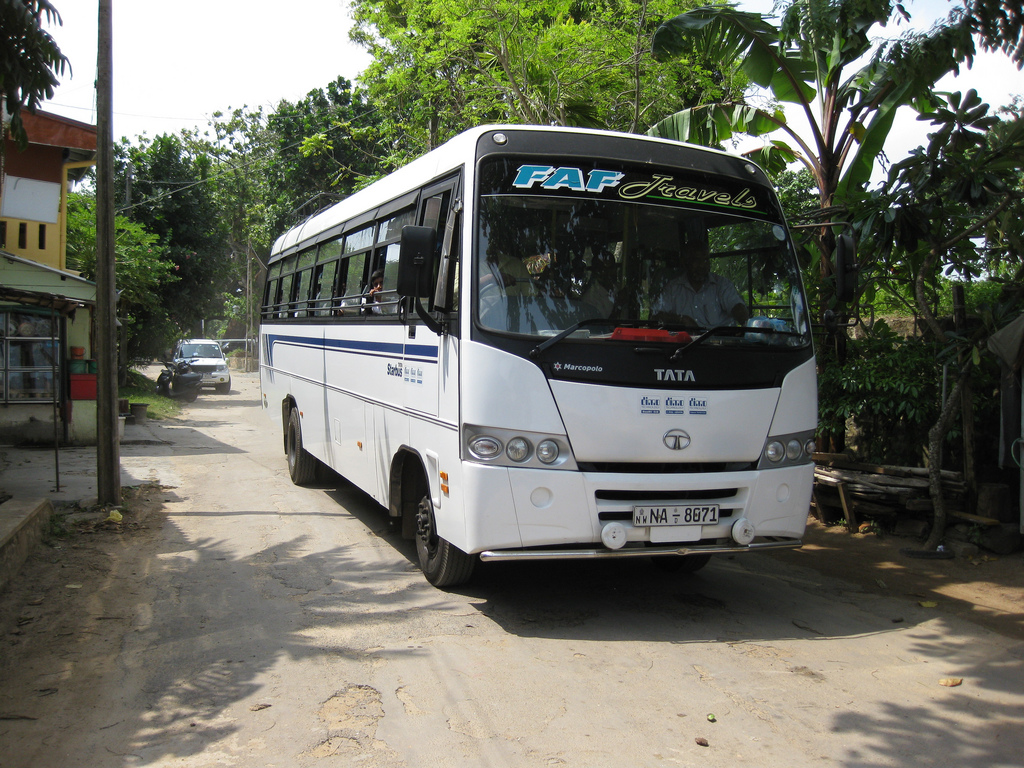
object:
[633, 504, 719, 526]
license plate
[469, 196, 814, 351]
windshield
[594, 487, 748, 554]
grate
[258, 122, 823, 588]
bus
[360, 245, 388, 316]
window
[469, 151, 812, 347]
windshield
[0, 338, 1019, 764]
street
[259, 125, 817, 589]
bus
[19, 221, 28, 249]
window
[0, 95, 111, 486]
building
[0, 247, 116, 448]
building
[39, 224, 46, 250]
window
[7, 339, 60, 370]
window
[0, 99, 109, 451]
building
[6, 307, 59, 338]
window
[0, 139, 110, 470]
building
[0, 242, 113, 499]
building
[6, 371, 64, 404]
window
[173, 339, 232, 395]
car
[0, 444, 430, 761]
street